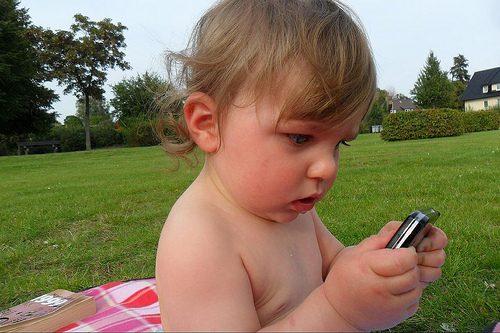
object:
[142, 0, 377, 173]
messy hair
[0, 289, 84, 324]
cover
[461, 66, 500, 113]
house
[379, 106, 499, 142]
hedges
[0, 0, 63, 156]
tree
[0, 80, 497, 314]
yard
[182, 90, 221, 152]
ear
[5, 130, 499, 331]
grass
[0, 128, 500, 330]
ground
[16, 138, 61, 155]
bench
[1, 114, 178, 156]
hedge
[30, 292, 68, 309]
title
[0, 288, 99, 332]
book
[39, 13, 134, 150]
tree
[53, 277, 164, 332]
blanket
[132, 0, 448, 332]
baby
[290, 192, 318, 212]
lip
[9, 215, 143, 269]
banket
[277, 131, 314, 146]
eyes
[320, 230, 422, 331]
hand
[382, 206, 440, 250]
cell phone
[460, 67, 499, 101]
roof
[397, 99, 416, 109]
roof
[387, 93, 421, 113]
home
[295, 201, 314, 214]
drowl